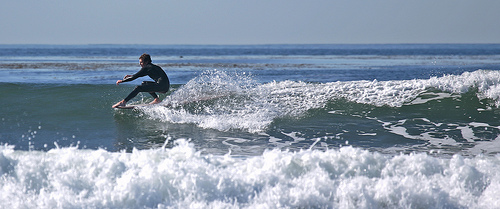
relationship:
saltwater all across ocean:
[193, 69, 310, 201] [7, 40, 485, 190]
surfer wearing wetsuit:
[110, 52, 169, 109] [115, 50, 177, 133]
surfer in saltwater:
[110, 52, 169, 109] [0, 43, 500, 208]